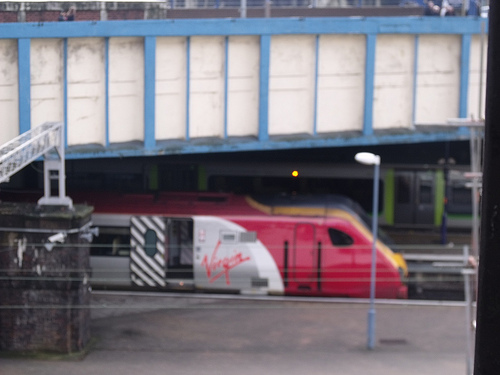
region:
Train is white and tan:
[100, 209, 289, 302]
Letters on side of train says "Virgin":
[194, 236, 255, 291]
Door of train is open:
[159, 215, 204, 293]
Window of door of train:
[138, 220, 160, 264]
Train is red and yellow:
[263, 203, 418, 293]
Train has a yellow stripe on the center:
[250, 199, 415, 309]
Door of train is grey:
[390, 166, 437, 232]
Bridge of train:
[7, 5, 488, 165]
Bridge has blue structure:
[0, 7, 481, 168]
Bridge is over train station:
[13, 3, 490, 207]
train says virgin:
[196, 233, 297, 338]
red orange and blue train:
[267, 189, 389, 282]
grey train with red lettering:
[173, 224, 264, 317]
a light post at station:
[311, 139, 403, 373]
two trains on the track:
[163, 161, 393, 326]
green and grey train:
[379, 161, 449, 246]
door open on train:
[100, 203, 340, 363]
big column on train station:
[4, 214, 128, 372]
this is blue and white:
[113, 91, 228, 185]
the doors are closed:
[388, 165, 453, 257]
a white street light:
[353, 150, 382, 167]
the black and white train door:
[129, 215, 165, 290]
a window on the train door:
[141, 228, 160, 255]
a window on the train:
[325, 225, 357, 248]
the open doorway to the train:
[164, 214, 194, 291]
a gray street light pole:
[362, 161, 384, 348]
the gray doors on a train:
[393, 167, 437, 226]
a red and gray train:
[84, 187, 412, 302]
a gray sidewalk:
[1, 286, 477, 373]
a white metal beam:
[1, 121, 74, 211]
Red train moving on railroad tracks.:
[23, 189, 407, 295]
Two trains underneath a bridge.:
[92, 156, 477, 297]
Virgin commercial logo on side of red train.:
[195, 239, 260, 289]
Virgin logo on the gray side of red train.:
[195, 238, 256, 288]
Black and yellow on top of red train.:
[245, 188, 410, 278]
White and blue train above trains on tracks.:
[5, 3, 484, 159]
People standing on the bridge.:
[0, 0, 490, 20]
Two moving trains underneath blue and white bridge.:
[94, 158, 470, 298]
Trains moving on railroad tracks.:
[78, 161, 473, 299]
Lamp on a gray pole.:
[354, 150, 386, 353]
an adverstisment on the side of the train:
[198, 246, 252, 286]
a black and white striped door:
[130, 220, 180, 295]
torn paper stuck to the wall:
[19, 225, 68, 274]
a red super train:
[279, 211, 400, 296]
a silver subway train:
[355, 169, 483, 229]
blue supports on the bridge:
[110, 28, 479, 133]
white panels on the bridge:
[166, 46, 216, 134]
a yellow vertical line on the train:
[434, 169, 446, 224]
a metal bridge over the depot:
[0, 119, 65, 166]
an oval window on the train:
[137, 226, 162, 260]